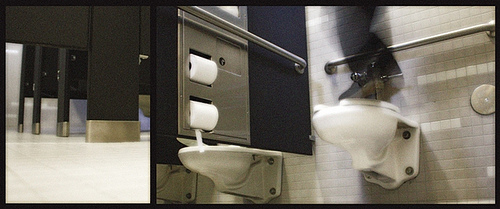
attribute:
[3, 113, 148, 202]
floor — tiled, white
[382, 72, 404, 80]
lever — silver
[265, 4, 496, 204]
tiles — grey, white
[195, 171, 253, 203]
tiles — grey, white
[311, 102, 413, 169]
bowl — curved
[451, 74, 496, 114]
lid — metal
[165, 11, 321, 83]
handlebar — metal, silver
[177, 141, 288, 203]
toilet — white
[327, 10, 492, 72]
handlebar — silver, metal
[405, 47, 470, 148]
tiles — grey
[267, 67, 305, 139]
wall — black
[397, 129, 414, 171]
panel — flat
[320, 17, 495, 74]
bar — silver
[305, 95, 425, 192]
toilet — white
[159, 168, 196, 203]
toilet — white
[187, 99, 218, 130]
toilet paper — white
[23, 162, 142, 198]
tile — white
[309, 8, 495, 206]
wall — tiled, white, gray